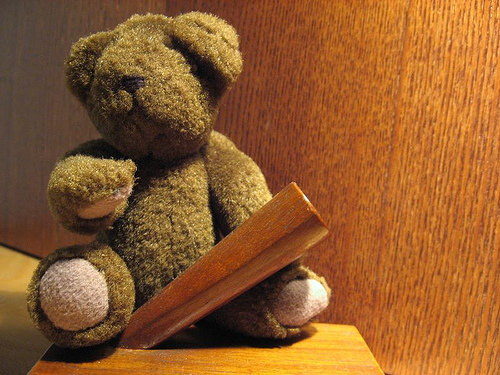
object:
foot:
[25, 246, 135, 349]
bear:
[25, 11, 334, 347]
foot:
[263, 266, 333, 339]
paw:
[69, 158, 134, 220]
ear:
[65, 31, 109, 104]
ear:
[164, 12, 246, 85]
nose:
[116, 74, 147, 93]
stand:
[23, 322, 385, 374]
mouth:
[156, 111, 206, 136]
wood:
[119, 180, 333, 351]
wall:
[0, 0, 500, 374]